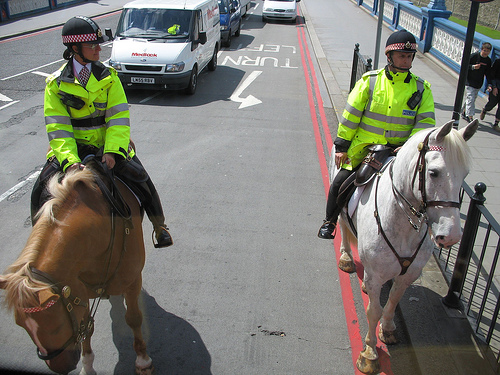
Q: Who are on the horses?
A: Police officers.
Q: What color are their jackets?
A: Green.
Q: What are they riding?
A: Horses.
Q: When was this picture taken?
A: During the day.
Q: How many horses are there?
A: Two.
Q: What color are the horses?
A: White and brown.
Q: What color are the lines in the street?
A: Red.